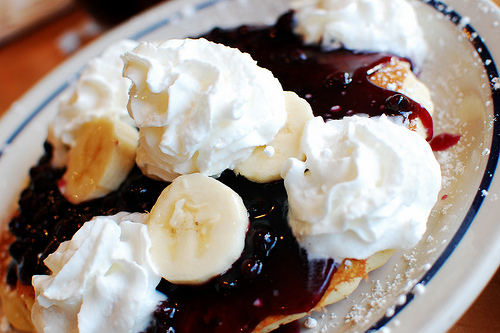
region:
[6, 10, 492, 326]
dessert with many types of sweet toppings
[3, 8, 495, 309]
white oval plate with blue band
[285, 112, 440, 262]
ball of ruffled whipped cream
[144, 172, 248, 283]
slice of creamy banana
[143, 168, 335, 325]
gooey blueberry sauce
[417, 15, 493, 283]
white powdered sugar on edge of plate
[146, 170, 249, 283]
a thin banana slice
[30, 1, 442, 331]
five piles of whipped cream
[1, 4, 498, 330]
a round white plate with a blue trim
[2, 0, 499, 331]
powdered sugar laying on a plate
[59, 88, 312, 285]
three slices of bananas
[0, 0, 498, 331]
a brown wooden table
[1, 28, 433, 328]
a round brown pancake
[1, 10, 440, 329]
a pancake covered with fruity syrup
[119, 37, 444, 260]
banana under a pile of whipped cream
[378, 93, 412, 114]
a dark colored berry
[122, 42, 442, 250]
Cakes in the photo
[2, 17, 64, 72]
A wooden table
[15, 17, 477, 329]
Cakes on a white plate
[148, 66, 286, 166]
Icing on the plate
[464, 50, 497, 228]
Blue line on the plate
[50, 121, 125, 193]
A slice of a banana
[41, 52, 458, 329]
Cakes placed on the table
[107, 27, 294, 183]
Whipped cream on the delicious pancake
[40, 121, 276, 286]
Bananas on top of the sauce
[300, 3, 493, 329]
Plate dusted with confectioner's sugar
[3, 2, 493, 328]
Pancake served on the plate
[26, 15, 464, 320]
berries and sauce on the pancake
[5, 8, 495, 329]
Pancake covered with sweet toppings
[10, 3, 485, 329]
5 dollops of whipped cream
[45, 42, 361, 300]
3 bananas on the pancake are seen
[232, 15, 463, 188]
Sauce dripping onto the plate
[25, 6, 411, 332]
whipped cream on the pancakes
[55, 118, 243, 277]
slices of banana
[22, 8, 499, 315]
powdered sugar on the plate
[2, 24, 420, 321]
stack of pancakes on the plate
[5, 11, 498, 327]
table the plate is on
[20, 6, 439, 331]
stack of pancakes with topping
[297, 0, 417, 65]
whipped cream sliding off the pancakes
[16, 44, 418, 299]
this is a breakfast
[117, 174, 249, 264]
this is a banana slice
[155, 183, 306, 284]
the slice is yellow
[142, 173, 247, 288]
slice of a banana on top of a pancake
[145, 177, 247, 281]
slice of banana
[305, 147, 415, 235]
cream is white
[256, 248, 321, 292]
jelly on the pancake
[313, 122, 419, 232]
whipped cream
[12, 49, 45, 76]
table is brown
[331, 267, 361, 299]
side of the pancake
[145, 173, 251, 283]
one small, round banana slice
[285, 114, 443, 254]
one dollop of whipped cream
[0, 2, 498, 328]
one round white plate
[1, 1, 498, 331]
white plate with blue rim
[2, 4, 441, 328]
pancake with blueberry syrup, whipped cream and bananas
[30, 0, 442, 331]
whipped cream on pancakes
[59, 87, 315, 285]
banana slices on syrup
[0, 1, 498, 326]
breakfast food on a plate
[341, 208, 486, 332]
powdered sugar on a plate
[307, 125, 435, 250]
a dollop of whipped cream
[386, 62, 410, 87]
pancake with powered sugar